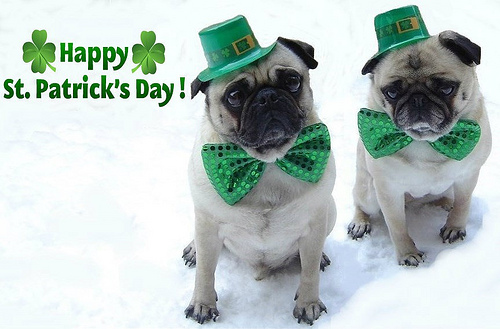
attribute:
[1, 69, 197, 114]
st. patrick's day — here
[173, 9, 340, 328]
dog — dressed up, black, white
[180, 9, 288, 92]
irish hat — green, plastic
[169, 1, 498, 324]
two dogs — white, dressed up, beige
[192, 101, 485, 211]
bowties — green, shiny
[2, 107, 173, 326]
background — white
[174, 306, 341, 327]
nails — black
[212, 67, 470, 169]
pug faces — cute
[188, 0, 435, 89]
hats — green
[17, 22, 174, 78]
two four leaf clover — green, here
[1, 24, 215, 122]
writing — green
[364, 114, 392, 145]
sequins — green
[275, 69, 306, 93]
eye — black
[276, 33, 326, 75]
ear — black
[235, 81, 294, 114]
snout — black